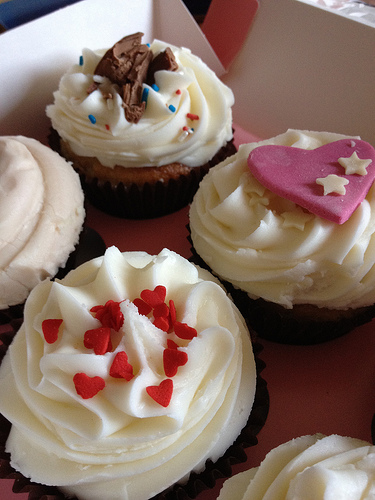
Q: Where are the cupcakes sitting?
A: In box.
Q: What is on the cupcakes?
A: Frosting.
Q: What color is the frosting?
A: White.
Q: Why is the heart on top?
A: Decor.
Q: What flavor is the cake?
A: Chocolate.